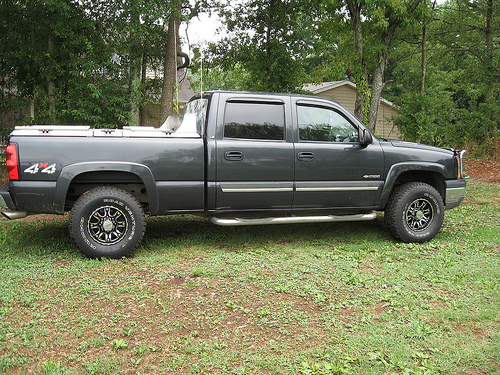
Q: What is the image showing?
A: It is showing a yard.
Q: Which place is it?
A: It is a yard.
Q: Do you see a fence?
A: No, there are no fences.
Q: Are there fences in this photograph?
A: No, there are no fences.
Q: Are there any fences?
A: No, there are no fences.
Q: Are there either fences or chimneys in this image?
A: No, there are no fences or chimneys.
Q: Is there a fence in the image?
A: No, there are no fences.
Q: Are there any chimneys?
A: No, there are no chimneys.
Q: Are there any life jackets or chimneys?
A: No, there are no chimneys or life jackets.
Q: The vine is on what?
A: The vine is on the tree.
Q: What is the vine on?
A: The vine is on the tree.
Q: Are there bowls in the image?
A: No, there are no bowls.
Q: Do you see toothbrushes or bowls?
A: No, there are no bowls or toothbrushes.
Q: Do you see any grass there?
A: Yes, there is grass.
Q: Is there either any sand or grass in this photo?
A: Yes, there is grass.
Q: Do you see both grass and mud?
A: No, there is grass but no mud.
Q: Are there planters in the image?
A: No, there are no planters.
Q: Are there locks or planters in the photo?
A: No, there are no planters or locks.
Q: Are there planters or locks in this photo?
A: No, there are no planters or locks.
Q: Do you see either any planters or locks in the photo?
A: No, there are no planters or locks.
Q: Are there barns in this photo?
A: No, there are no barns.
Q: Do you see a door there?
A: Yes, there is a door.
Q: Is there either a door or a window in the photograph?
A: Yes, there is a door.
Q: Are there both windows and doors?
A: Yes, there are both a door and windows.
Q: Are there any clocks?
A: No, there are no clocks.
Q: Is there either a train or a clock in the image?
A: No, there are no clocks or trains.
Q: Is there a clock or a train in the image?
A: No, there are no clocks or trains.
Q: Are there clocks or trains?
A: No, there are no clocks or trains.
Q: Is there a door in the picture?
A: Yes, there is a door.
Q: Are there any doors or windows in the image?
A: Yes, there is a door.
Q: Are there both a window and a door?
A: Yes, there are both a door and a window.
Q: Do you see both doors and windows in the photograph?
A: Yes, there are both a door and windows.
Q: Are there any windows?
A: Yes, there is a window.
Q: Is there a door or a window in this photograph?
A: Yes, there is a window.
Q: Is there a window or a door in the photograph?
A: Yes, there is a window.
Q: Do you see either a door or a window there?
A: Yes, there is a window.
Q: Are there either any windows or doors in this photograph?
A: Yes, there is a window.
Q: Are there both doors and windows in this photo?
A: Yes, there are both a window and a door.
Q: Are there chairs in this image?
A: No, there are no chairs.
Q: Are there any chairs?
A: No, there are no chairs.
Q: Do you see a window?
A: Yes, there is a window.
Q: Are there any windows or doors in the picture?
A: Yes, there is a window.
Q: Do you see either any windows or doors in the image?
A: Yes, there is a window.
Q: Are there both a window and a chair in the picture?
A: No, there is a window but no chairs.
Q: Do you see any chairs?
A: No, there are no chairs.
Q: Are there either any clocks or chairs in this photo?
A: No, there are no chairs or clocks.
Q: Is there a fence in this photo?
A: No, there are no fences.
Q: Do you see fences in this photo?
A: No, there are no fences.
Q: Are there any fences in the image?
A: No, there are no fences.